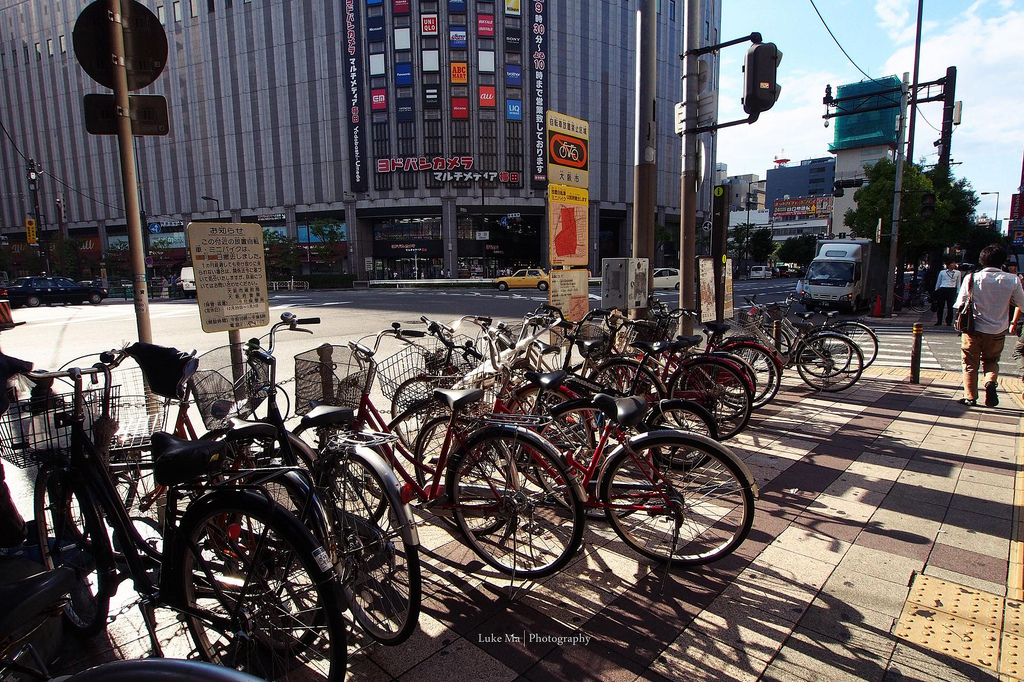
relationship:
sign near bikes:
[181, 210, 273, 340] [3, 296, 878, 677]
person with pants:
[950, 241, 1020, 407] [950, 241, 1020, 407]